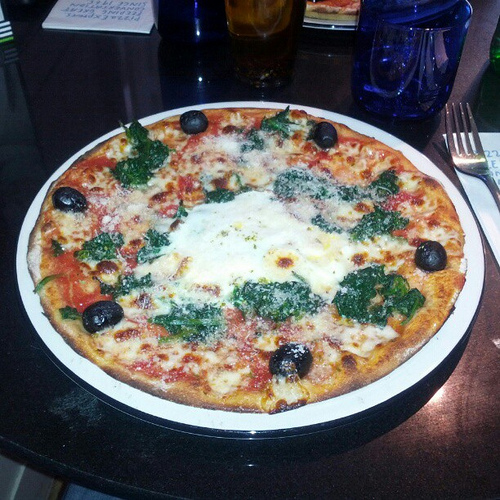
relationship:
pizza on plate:
[34, 125, 472, 370] [14, 87, 489, 441]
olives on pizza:
[60, 108, 444, 380] [34, 125, 472, 370]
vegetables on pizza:
[117, 136, 409, 328] [34, 125, 472, 370]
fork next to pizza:
[425, 97, 500, 229] [34, 125, 472, 370]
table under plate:
[2, 2, 499, 498] [14, 87, 489, 441]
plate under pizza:
[14, 87, 489, 441] [34, 125, 472, 370]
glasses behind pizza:
[143, 0, 472, 127] [34, 125, 472, 370]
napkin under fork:
[438, 130, 500, 293] [425, 97, 500, 229]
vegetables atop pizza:
[117, 136, 409, 328] [34, 125, 472, 370]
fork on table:
[425, 97, 500, 229] [2, 2, 499, 498]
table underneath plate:
[2, 2, 499, 498] [14, 87, 489, 441]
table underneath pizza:
[2, 2, 499, 498] [34, 125, 472, 370]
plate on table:
[14, 87, 489, 441] [2, 2, 499, 498]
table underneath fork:
[2, 2, 499, 498] [425, 97, 500, 229]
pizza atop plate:
[34, 125, 472, 370] [14, 87, 489, 441]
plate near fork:
[14, 87, 489, 441] [425, 97, 500, 229]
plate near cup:
[14, 87, 489, 441] [353, 2, 476, 129]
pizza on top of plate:
[34, 125, 472, 370] [14, 87, 489, 441]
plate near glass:
[14, 87, 489, 441] [213, 0, 314, 92]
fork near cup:
[425, 97, 500, 229] [353, 2, 476, 129]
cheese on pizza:
[154, 191, 357, 302] [34, 125, 472, 370]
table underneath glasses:
[2, 2, 499, 498] [143, 0, 472, 127]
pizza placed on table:
[34, 125, 472, 370] [2, 2, 499, 498]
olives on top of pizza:
[60, 108, 444, 380] [34, 125, 472, 370]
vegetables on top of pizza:
[117, 136, 409, 328] [34, 125, 472, 370]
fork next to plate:
[425, 97, 500, 229] [14, 87, 489, 441]